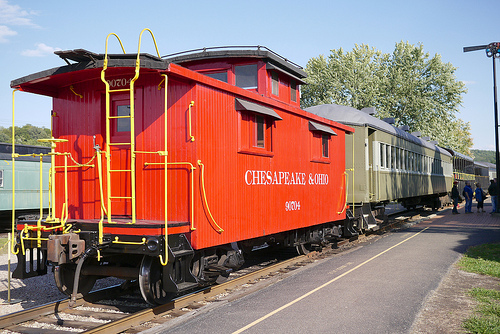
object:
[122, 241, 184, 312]
wheel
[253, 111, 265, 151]
window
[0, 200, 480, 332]
tracks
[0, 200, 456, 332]
train tracks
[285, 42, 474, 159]
tree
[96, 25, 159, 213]
ladder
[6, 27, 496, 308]
train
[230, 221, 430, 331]
line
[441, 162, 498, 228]
people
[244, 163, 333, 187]
name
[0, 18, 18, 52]
cloud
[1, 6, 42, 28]
cloud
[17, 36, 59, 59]
cloud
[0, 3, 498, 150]
sky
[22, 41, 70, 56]
clouds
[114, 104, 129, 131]
window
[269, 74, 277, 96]
window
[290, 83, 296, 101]
window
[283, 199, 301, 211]
number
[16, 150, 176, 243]
stand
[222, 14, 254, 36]
clouds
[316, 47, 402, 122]
leaves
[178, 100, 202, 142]
handle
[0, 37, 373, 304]
caboose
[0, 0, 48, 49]
white clouds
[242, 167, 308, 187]
written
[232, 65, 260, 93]
window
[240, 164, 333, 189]
text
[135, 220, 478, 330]
pavement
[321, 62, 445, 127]
trees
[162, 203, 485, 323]
road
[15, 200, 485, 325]
ground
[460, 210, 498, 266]
standing